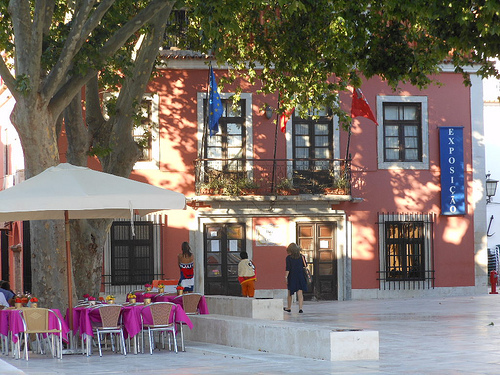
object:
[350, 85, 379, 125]
flag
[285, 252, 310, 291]
dress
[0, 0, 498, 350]
tree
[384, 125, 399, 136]
window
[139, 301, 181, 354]
chair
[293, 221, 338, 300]
door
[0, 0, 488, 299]
building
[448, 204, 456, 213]
letters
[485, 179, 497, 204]
lantern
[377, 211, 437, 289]
cage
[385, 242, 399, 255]
window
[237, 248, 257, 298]
woman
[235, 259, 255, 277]
shirt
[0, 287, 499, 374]
walkway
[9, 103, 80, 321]
trunk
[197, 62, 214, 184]
pole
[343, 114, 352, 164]
pole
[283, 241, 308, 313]
woman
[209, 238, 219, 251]
paper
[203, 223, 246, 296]
door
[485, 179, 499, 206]
lamp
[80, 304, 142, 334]
tablecloth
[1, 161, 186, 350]
umbrella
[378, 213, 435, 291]
gate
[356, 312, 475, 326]
shadow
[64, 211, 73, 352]
pole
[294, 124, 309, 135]
window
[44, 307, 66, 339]
cloth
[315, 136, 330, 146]
sections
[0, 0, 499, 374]
outdoor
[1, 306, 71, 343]
tablecloth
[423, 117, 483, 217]
banner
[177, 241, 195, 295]
lady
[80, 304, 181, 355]
tables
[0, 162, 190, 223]
gazibo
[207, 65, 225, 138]
flag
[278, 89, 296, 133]
flag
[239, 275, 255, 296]
pants